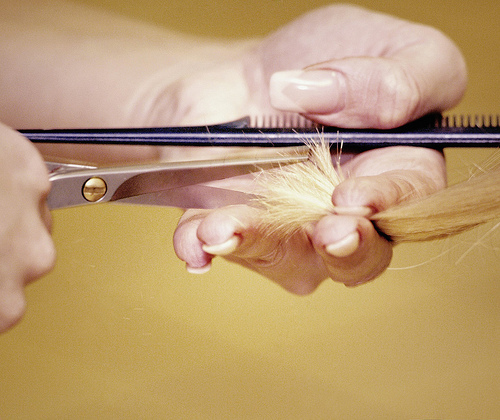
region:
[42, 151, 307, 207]
Scissors cutting a portion of hair.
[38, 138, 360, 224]
a pair of scissors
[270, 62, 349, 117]
a finger nail on a finger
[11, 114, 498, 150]
a black comb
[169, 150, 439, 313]
fingers holding hair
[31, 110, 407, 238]
scissors cutting hair ends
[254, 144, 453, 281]
Two fingers holding hair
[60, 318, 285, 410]
A gold back ground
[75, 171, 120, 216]
A brass screw in the scissors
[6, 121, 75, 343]
knuckles of the right hand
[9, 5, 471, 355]
A pair of hands cutting hair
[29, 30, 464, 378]
A woman cutting hair.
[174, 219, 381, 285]
Long finger nails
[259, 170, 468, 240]
hair is blond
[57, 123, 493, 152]
she holds a comb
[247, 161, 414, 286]
hair is in between fingers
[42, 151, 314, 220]
Scissors in her right hand.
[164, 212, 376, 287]
Her nails are manicured.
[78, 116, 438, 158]
The comb is black in color.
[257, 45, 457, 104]
The top of her thumb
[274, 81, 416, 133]
Thumb is on the comb.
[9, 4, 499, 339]
Hairdresser hands trimming blonde hair.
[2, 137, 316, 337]
Right hand controls scissors.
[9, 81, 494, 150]
Black comb between fingers.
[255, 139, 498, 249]
Customer blond hair between fingertips.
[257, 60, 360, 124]
Well manicured shiny fingernails.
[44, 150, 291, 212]
High end beautician scissors.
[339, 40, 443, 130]
Taut knuckles steady comb.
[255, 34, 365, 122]
Light reflected off fingernail.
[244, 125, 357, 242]
Blond hair ends need shaping.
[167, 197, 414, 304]
Fingers dry skin benefit moisturizer.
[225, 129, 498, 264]
blond hair that the woman is trimming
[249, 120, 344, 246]
split ends of blond hair being clipped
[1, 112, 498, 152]
black comb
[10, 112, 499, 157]
black comb in the beauticians hand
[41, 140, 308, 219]
stainless steel scissors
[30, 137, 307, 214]
scissors in the beauticians hands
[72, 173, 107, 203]
gold colored screw in the scissors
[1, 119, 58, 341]
beauticians right hand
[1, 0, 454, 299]
beauticians left arm and hand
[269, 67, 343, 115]
well manicured fingernail